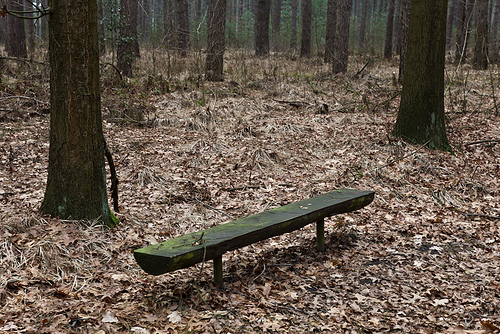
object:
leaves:
[164, 309, 183, 326]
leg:
[313, 214, 327, 250]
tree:
[328, 0, 351, 75]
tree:
[201, 0, 228, 84]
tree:
[250, 0, 270, 59]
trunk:
[389, 0, 454, 158]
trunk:
[327, 0, 349, 74]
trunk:
[200, 0, 228, 84]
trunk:
[39, 0, 117, 228]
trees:
[113, 0, 138, 76]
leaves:
[109, 271, 130, 281]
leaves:
[428, 243, 443, 256]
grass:
[0, 44, 499, 333]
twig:
[193, 229, 208, 290]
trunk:
[113, 0, 141, 77]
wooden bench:
[130, 186, 378, 287]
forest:
[0, 0, 499, 333]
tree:
[390, 0, 456, 153]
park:
[0, 1, 499, 333]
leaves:
[427, 296, 449, 308]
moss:
[424, 111, 455, 150]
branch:
[2, 6, 44, 23]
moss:
[101, 190, 119, 228]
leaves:
[259, 183, 276, 195]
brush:
[0, 45, 50, 120]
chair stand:
[210, 252, 225, 289]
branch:
[103, 144, 123, 213]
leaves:
[356, 272, 377, 284]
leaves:
[250, 279, 272, 300]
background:
[0, 1, 497, 333]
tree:
[39, 0, 117, 228]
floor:
[0, 46, 498, 333]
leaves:
[400, 289, 420, 307]